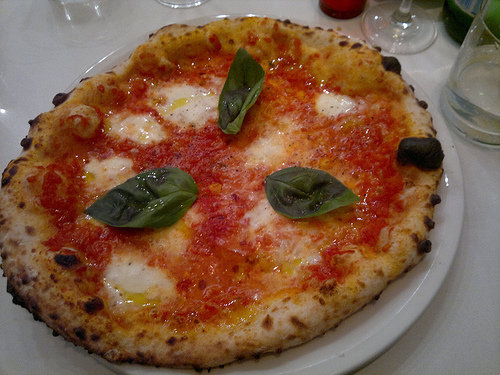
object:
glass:
[440, 1, 500, 147]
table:
[1, 0, 499, 375]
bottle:
[439, 1, 500, 48]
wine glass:
[360, 0, 436, 57]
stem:
[362, 0, 438, 57]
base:
[361, 4, 437, 55]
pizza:
[2, 16, 444, 371]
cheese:
[0, 16, 448, 317]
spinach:
[84, 168, 200, 227]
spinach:
[217, 44, 265, 135]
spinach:
[263, 167, 360, 219]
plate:
[0, 11, 464, 373]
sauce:
[41, 41, 392, 321]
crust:
[0, 14, 446, 371]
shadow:
[349, 201, 460, 375]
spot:
[395, 135, 445, 172]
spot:
[428, 191, 442, 204]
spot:
[423, 215, 435, 229]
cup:
[317, 1, 366, 21]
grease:
[115, 284, 157, 309]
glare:
[84, 45, 121, 73]